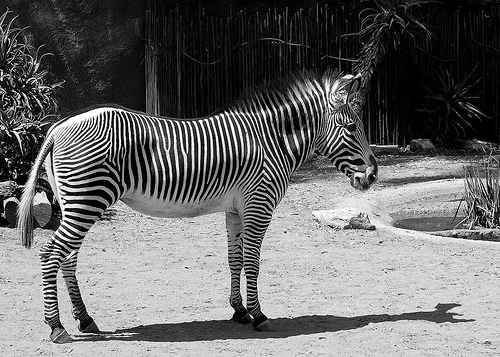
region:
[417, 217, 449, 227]
Water in a drinking hole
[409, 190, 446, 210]
A water hole in the ground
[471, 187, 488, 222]
Plants in the water hole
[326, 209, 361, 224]
A piece of rock on the ground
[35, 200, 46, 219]
A piece of rock next to the tail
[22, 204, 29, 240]
The tail of a zebra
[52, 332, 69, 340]
The hoof a zebra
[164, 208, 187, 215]
The white underside of a zebra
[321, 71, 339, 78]
The mane on a zebra head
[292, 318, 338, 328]
The shadow cast by the zebra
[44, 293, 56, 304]
black stripe on zebra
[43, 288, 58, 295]
black stripe on zebra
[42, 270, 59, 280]
black stripe on zebra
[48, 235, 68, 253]
black stripe on zebra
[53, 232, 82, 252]
black stripe on zebra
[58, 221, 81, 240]
black stripe on zebra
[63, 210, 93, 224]
black stripe on zebra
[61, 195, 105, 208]
black stripe on zebra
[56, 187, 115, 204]
black stripe on zebra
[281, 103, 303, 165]
black stripe on zebra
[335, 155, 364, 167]
black stripe on zebra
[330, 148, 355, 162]
black stripe on zebra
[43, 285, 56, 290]
black stripe on zebra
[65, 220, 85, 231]
black stripe on zebra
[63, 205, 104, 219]
black stripe on zebra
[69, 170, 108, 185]
black stripe on zebra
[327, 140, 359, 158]
black stripe on zebra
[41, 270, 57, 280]
black stripe on zebra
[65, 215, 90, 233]
black stripe on zebra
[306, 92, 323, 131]
black stripe on zebra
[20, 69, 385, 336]
a single zebra at a zoo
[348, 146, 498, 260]
the drinking water for the zebra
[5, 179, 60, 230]
a pile of wood in the zebra habitat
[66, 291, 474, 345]
the zebra's shadow in the dirt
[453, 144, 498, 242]
reeds in the drinking pond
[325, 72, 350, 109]
the zebra's right ear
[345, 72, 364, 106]
the zebra's left ear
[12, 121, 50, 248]
the zebra's tail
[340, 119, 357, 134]
the zebra's right eye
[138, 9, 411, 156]
the wall of the zebra habitat